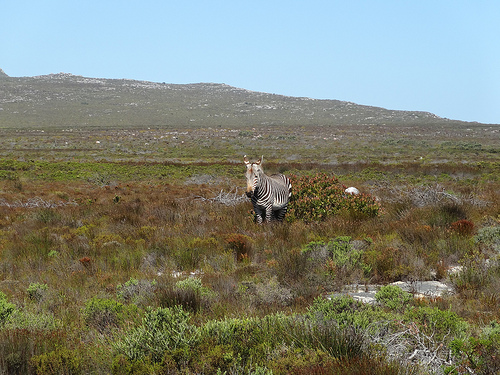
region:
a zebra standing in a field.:
[230, 147, 302, 222]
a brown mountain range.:
[0, 68, 493, 144]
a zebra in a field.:
[333, 173, 376, 222]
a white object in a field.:
[83, 133, 110, 155]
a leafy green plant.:
[98, 298, 498, 365]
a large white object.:
[339, 176, 374, 208]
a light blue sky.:
[0, 3, 497, 128]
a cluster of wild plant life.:
[66, 264, 213, 326]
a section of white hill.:
[249, 98, 284, 124]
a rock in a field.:
[297, 278, 459, 313]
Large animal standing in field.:
[221, 159, 341, 321]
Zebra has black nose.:
[236, 182, 259, 220]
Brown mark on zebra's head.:
[247, 162, 267, 195]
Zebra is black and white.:
[219, 157, 317, 249]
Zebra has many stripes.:
[238, 163, 295, 270]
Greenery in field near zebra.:
[144, 310, 412, 365]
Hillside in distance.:
[103, 98, 462, 149]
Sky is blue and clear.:
[286, 42, 425, 94]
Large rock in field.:
[325, 275, 445, 300]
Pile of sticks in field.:
[171, 174, 243, 228]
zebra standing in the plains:
[226, 146, 308, 233]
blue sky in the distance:
[4, 3, 491, 66]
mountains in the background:
[3, 68, 487, 143]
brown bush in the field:
[220, 227, 260, 270]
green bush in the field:
[197, 315, 278, 363]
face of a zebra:
[241, 153, 271, 200]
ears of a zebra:
[236, 150, 268, 168]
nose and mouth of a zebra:
[244, 183, 256, 200]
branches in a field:
[395, 328, 445, 360]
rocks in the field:
[420, 279, 451, 296]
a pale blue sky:
[1, 3, 494, 124]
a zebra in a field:
[240, 150, 301, 240]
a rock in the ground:
[390, 270, 457, 305]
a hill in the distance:
[1, 66, 467, 156]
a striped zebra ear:
[242, 153, 253, 167]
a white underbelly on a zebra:
[270, 198, 287, 210]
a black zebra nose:
[244, 190, 255, 199]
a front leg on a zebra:
[261, 203, 274, 229]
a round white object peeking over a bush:
[340, 182, 369, 200]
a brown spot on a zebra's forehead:
[249, 166, 257, 179]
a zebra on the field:
[224, 122, 336, 233]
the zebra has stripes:
[238, 155, 307, 230]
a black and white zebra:
[240, 149, 308, 210]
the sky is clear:
[49, 11, 401, 66]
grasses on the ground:
[48, 163, 351, 305]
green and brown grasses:
[99, 205, 315, 317]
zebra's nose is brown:
[244, 179, 260, 211]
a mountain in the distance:
[27, 50, 394, 152]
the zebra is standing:
[230, 148, 299, 243]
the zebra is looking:
[210, 133, 295, 228]